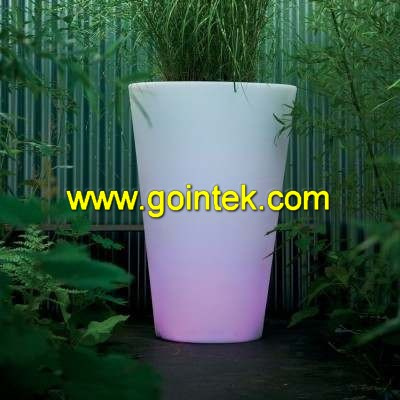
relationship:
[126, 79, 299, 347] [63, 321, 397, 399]
planter on ground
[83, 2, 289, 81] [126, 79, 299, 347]
foliage in planter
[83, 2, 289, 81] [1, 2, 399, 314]
foliage by wall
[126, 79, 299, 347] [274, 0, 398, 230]
planter by tree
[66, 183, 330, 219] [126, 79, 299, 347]
website over planter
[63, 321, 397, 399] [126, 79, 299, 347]
ground under planter